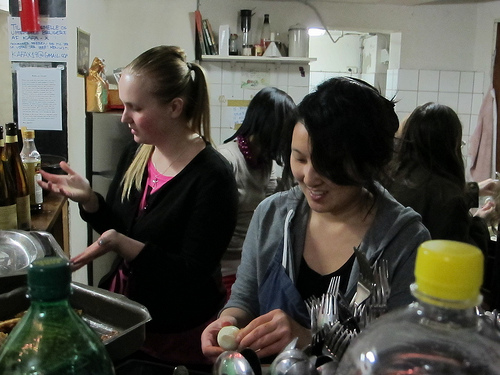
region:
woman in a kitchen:
[18, 29, 499, 369]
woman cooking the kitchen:
[29, 26, 486, 371]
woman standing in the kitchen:
[48, 23, 465, 373]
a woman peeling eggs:
[136, 18, 489, 372]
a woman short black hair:
[242, 38, 379, 246]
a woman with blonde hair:
[67, 36, 278, 332]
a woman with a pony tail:
[61, 8, 326, 302]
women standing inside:
[41, 12, 472, 374]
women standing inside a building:
[33, 33, 473, 374]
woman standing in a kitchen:
[22, 25, 470, 366]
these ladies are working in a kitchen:
[3, 15, 480, 372]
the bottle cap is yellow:
[414, 236, 494, 311]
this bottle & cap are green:
[6, 249, 112, 371]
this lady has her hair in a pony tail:
[104, 48, 229, 218]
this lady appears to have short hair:
[286, 62, 401, 222]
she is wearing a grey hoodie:
[234, 55, 424, 332]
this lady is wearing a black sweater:
[107, 117, 254, 296]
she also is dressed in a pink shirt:
[128, 140, 170, 224]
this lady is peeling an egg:
[189, 270, 305, 368]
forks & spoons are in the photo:
[211, 243, 394, 373]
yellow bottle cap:
[405, 233, 483, 304]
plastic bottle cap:
[410, 231, 485, 319]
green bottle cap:
[20, 256, 72, 296]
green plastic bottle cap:
[28, 249, 73, 310]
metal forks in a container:
[294, 242, 395, 354]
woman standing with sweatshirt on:
[204, 61, 426, 371]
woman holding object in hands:
[192, 301, 306, 363]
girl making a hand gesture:
[27, 49, 224, 316]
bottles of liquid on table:
[0, 113, 51, 228]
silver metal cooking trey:
[24, 271, 149, 373]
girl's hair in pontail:
[113, 31, 235, 183]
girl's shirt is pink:
[130, 165, 175, 203]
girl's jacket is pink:
[108, 154, 255, 309]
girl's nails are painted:
[90, 229, 118, 256]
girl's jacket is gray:
[252, 174, 436, 325]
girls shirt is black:
[295, 251, 375, 308]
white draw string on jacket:
[280, 200, 298, 278]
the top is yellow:
[389, 222, 489, 317]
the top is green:
[18, 236, 82, 308]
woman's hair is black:
[230, 73, 292, 162]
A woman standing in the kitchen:
[30, 39, 237, 365]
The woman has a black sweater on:
[78, 139, 239, 336]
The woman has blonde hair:
[108, 41, 230, 206]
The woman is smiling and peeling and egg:
[200, 73, 434, 370]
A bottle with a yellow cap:
[336, 225, 495, 371]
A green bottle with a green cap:
[3, 236, 123, 373]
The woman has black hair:
[286, 73, 402, 215]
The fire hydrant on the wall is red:
[14, 1, 43, 34]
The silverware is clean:
[210, 257, 395, 373]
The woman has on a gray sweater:
[212, 85, 299, 305]